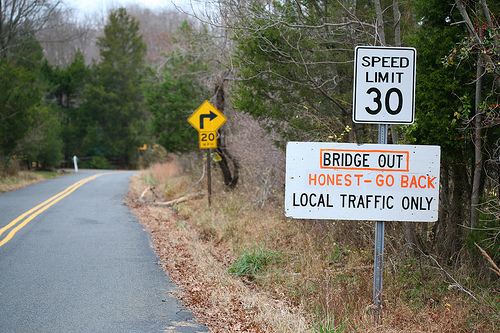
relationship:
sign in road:
[135, 138, 153, 155] [2, 170, 212, 330]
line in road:
[4, 171, 101, 241] [1, 162, 191, 332]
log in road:
[139, 183, 206, 206] [2, 170, 212, 330]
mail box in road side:
[69, 154, 81, 171] [0, 167, 215, 329]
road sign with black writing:
[351, 46, 416, 125] [358, 53, 412, 70]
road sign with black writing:
[351, 46, 416, 125] [365, 69, 402, 84]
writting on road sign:
[359, 57, 409, 114] [351, 44, 416, 124]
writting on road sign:
[292, 152, 437, 211] [284, 140, 441, 221]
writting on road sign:
[200, 110, 217, 147] [284, 140, 441, 221]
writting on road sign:
[309, 148, 435, 188] [186, 97, 227, 149]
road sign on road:
[187, 99, 227, 149] [1, 152, 204, 329]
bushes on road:
[163, 149, 475, 326] [2, 170, 212, 330]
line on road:
[0, 173, 103, 250] [78, 170, 116, 325]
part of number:
[367, 87, 382, 100] [369, 87, 398, 119]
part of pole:
[373, 221, 382, 305] [372, 124, 387, 311]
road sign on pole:
[284, 142, 441, 222] [355, 124, 405, 311]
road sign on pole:
[351, 46, 416, 125] [355, 124, 405, 311]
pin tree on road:
[0, 7, 202, 170] [2, 170, 212, 330]